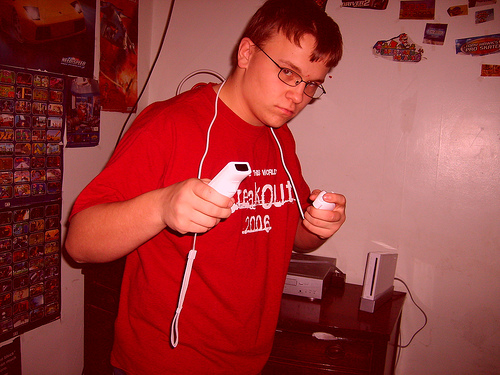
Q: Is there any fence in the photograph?
A: No, there are no fences.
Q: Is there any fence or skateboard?
A: No, there are no fences or skateboards.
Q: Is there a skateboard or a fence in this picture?
A: No, there are no fences or skateboards.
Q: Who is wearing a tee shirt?
A: The boy is wearing a tee shirt.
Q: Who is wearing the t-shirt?
A: The boy is wearing a tee shirt.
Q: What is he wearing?
A: The boy is wearing a tshirt.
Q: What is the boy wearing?
A: The boy is wearing a tshirt.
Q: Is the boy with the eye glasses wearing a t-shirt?
A: Yes, the boy is wearing a t-shirt.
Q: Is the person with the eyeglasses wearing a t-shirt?
A: Yes, the boy is wearing a t-shirt.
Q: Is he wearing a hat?
A: No, the boy is wearing a t-shirt.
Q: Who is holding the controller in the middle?
A: The boy is holding the controller.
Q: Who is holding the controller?
A: The boy is holding the controller.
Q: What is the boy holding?
A: The boy is holding the controller.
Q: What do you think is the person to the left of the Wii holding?
A: The boy is holding the controller.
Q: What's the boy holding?
A: The boy is holding the controller.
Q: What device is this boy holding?
A: The boy is holding the controller.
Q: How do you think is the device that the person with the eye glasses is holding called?
A: The device is a controller.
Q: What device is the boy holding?
A: The boy is holding the controller.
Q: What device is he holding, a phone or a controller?
A: The boy is holding a controller.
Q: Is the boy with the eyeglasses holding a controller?
A: Yes, the boy is holding a controller.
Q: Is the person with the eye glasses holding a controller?
A: Yes, the boy is holding a controller.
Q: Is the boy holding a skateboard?
A: No, the boy is holding a controller.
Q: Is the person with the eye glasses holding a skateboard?
A: No, the boy is holding a controller.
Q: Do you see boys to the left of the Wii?
A: Yes, there is a boy to the left of the Wii.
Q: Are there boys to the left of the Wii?
A: Yes, there is a boy to the left of the Wii.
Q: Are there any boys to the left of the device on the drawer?
A: Yes, there is a boy to the left of the Wii.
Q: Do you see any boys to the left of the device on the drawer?
A: Yes, there is a boy to the left of the Wii.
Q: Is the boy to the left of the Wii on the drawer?
A: Yes, the boy is to the left of the Wii.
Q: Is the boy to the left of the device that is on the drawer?
A: Yes, the boy is to the left of the Wii.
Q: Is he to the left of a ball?
A: No, the boy is to the left of the Wii.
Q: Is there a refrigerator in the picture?
A: No, there are no refrigerators.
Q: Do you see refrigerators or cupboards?
A: No, there are no refrigerators or cupboards.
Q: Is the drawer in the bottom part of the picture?
A: Yes, the drawer is in the bottom of the image.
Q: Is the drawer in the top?
A: No, the drawer is in the bottom of the image.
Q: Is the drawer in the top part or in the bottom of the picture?
A: The drawer is in the bottom of the image.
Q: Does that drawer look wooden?
A: Yes, the drawer is wooden.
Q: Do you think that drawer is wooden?
A: Yes, the drawer is wooden.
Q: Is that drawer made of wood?
A: Yes, the drawer is made of wood.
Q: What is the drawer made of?
A: The drawer is made of wood.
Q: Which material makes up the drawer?
A: The drawer is made of wood.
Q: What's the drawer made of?
A: The drawer is made of wood.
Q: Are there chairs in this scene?
A: No, there are no chairs.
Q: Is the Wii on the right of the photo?
A: Yes, the Wii is on the right of the image.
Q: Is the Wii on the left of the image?
A: No, the Wii is on the right of the image.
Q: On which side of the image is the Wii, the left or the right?
A: The Wii is on the right of the image.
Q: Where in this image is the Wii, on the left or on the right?
A: The Wii is on the right of the image.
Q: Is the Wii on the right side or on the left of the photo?
A: The Wii is on the right of the image.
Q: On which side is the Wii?
A: The Wii is on the right of the image.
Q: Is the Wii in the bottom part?
A: Yes, the Wii is in the bottom of the image.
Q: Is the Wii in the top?
A: No, the Wii is in the bottom of the image.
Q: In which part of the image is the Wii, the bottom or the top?
A: The Wii is in the bottom of the image.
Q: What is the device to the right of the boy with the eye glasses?
A: The device is a Wii.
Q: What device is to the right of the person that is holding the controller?
A: The device is a Wii.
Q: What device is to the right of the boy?
A: The device is a Wii.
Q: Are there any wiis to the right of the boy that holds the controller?
A: Yes, there is a Wii to the right of the boy.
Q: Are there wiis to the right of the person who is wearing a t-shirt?
A: Yes, there is a Wii to the right of the boy.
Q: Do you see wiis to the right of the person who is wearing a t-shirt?
A: Yes, there is a Wii to the right of the boy.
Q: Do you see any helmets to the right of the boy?
A: No, there is a Wii to the right of the boy.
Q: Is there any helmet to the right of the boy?
A: No, there is a Wii to the right of the boy.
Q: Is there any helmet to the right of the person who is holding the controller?
A: No, there is a Wii to the right of the boy.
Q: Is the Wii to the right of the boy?
A: Yes, the Wii is to the right of the boy.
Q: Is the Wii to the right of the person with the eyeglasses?
A: Yes, the Wii is to the right of the boy.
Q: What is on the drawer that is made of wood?
A: The Wii is on the drawer.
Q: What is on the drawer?
A: The Wii is on the drawer.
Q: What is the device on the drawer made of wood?
A: The device is a Wii.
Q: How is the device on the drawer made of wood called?
A: The device is a Wii.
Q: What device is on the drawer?
A: The device is a Wii.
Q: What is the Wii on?
A: The Wii is on the drawer.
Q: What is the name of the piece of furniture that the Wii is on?
A: The piece of furniture is a drawer.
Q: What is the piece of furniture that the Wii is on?
A: The piece of furniture is a drawer.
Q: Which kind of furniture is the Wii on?
A: The Wii is on the drawer.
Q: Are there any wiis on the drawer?
A: Yes, there is a Wii on the drawer.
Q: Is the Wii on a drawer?
A: Yes, the Wii is on a drawer.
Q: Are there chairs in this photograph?
A: No, there are no chairs.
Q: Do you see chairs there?
A: No, there are no chairs.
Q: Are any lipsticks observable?
A: No, there are no lipsticks.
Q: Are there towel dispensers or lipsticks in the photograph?
A: No, there are no lipsticks or towel dispensers.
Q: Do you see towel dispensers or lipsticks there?
A: No, there are no lipsticks or towel dispensers.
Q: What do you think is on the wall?
A: The stickers are on the wall.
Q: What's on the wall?
A: The stickers are on the wall.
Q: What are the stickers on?
A: The stickers are on the wall.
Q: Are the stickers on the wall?
A: Yes, the stickers are on the wall.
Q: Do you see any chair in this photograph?
A: No, there are no chairs.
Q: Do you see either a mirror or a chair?
A: No, there are no chairs or mirrors.